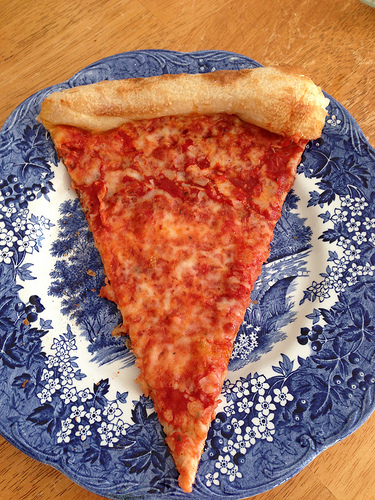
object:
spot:
[205, 70, 251, 87]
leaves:
[319, 213, 345, 248]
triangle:
[28, 60, 325, 495]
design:
[0, 46, 373, 492]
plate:
[0, 39, 373, 483]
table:
[2, 0, 375, 500]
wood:
[3, 3, 372, 499]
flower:
[46, 342, 128, 450]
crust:
[42, 65, 332, 134]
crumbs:
[19, 269, 110, 394]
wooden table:
[0, 0, 373, 500]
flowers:
[237, 374, 287, 434]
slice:
[38, 65, 331, 492]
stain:
[109, 369, 121, 380]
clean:
[289, 434, 374, 500]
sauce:
[47, 113, 309, 493]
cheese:
[40, 65, 330, 493]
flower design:
[6, 111, 374, 486]